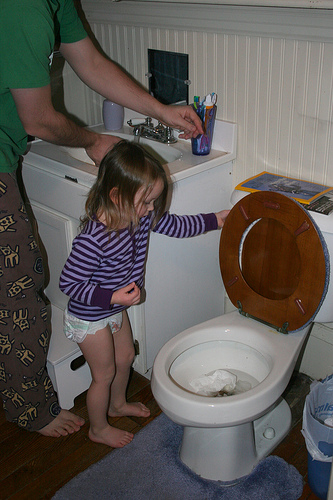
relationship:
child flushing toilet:
[62, 138, 231, 450] [149, 173, 333, 481]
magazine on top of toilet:
[234, 171, 332, 207] [149, 173, 333, 481]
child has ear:
[62, 138, 231, 450] [108, 185, 122, 207]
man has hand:
[0, 3, 205, 439] [160, 103, 206, 140]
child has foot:
[62, 138, 231, 450] [86, 425, 134, 450]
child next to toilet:
[62, 138, 231, 450] [149, 173, 333, 481]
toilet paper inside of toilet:
[186, 368, 238, 394] [149, 173, 333, 481]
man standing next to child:
[0, 3, 205, 439] [62, 138, 231, 450]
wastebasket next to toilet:
[302, 378, 332, 496] [149, 173, 333, 481]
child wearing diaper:
[62, 138, 231, 450] [63, 309, 122, 344]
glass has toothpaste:
[189, 104, 217, 156] [199, 95, 213, 153]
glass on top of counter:
[189, 104, 217, 156] [26, 118, 229, 183]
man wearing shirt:
[0, 3, 205, 439] [0, 0, 90, 175]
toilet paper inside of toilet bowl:
[186, 368, 238, 394] [165, 327, 277, 399]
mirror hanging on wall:
[145, 48, 190, 106] [32, 4, 331, 383]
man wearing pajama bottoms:
[0, 3, 205, 439] [0, 172, 63, 433]